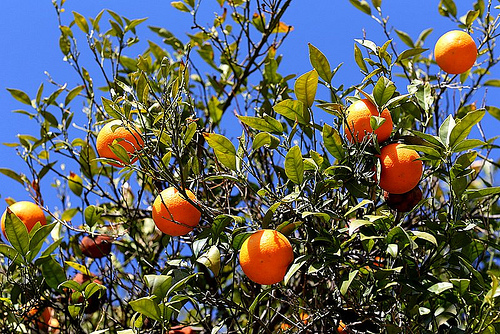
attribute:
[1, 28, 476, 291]
oranges — dark, growing, brown, rotten, shadowed, halved, separated, seven, second, middled, bright, topped, one, ripe, ready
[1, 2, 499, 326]
tree — branched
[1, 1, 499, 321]
leaves — green, veiny, dead, yellow, shadowy, thick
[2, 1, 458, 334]
sky — blue